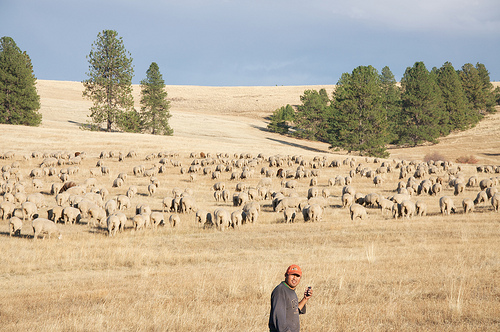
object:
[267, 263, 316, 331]
man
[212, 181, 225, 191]
sheep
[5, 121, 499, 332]
field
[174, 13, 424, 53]
sky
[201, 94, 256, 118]
grass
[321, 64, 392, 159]
trees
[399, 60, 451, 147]
trees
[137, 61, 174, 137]
tree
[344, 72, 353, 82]
leaves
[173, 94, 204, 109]
vegetation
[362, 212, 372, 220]
heard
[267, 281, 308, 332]
shirt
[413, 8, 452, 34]
cloud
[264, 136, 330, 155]
shadow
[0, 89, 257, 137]
ground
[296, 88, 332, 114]
shrubs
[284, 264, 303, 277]
cap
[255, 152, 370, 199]
flock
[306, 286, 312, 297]
cellphone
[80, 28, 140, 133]
tree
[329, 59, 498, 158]
group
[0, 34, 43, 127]
tree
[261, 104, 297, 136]
bushhes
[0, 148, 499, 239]
cluster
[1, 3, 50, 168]
side